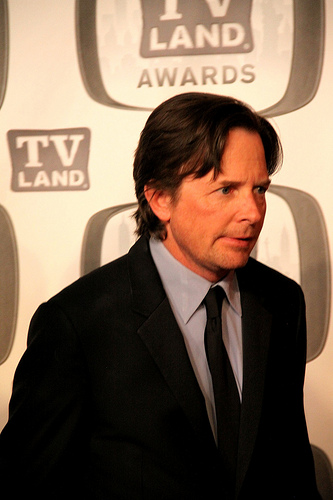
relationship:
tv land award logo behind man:
[6, 123, 95, 194] [5, 88, 315, 500]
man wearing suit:
[5, 88, 315, 500] [4, 235, 315, 500]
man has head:
[5, 88, 315, 500] [134, 95, 274, 273]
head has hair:
[134, 95, 274, 273] [129, 90, 284, 244]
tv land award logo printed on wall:
[6, 123, 95, 194] [3, 3, 332, 499]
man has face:
[5, 88, 315, 500] [200, 137, 268, 270]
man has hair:
[5, 88, 315, 500] [129, 90, 284, 244]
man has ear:
[5, 88, 315, 500] [145, 179, 171, 224]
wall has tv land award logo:
[3, 3, 332, 499] [6, 123, 95, 194]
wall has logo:
[3, 3, 332, 499] [133, 1, 267, 91]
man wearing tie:
[5, 88, 315, 500] [200, 279, 243, 465]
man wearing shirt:
[5, 88, 315, 500] [148, 233, 248, 459]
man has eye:
[5, 88, 315, 500] [221, 186, 233, 195]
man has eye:
[5, 88, 315, 500] [255, 186, 263, 193]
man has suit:
[5, 88, 315, 500] [4, 235, 315, 500]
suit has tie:
[4, 235, 315, 500] [200, 279, 243, 465]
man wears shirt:
[5, 88, 315, 500] [148, 233, 248, 459]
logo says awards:
[133, 1, 267, 91] [136, 62, 260, 87]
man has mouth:
[5, 88, 315, 500] [223, 232, 255, 247]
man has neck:
[5, 88, 315, 500] [161, 223, 226, 286]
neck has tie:
[161, 223, 226, 286] [200, 279, 243, 465]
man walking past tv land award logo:
[5, 88, 315, 500] [6, 123, 95, 194]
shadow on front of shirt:
[212, 279, 243, 337] [148, 233, 248, 459]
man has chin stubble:
[5, 88, 315, 500] [211, 247, 251, 272]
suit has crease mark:
[4, 235, 315, 500] [37, 392, 83, 460]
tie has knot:
[200, 279, 243, 465] [204, 284, 224, 320]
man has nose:
[5, 88, 315, 500] [234, 187, 261, 227]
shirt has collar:
[148, 233, 248, 459] [150, 236, 242, 323]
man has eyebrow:
[5, 88, 315, 500] [217, 176, 242, 191]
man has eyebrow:
[5, 88, 315, 500] [254, 176, 272, 189]